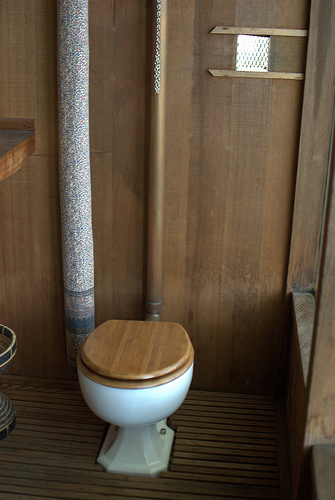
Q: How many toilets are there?
A: One.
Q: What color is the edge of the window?
A: Brown.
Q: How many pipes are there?
A: Two.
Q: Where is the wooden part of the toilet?
A: Lid.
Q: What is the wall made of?
A: Wood.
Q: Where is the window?
A: To the right.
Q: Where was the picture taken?
A: In a bathroom.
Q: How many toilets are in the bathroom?
A: 1.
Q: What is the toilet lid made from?
A: Wood.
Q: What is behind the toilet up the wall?
A: A pipe.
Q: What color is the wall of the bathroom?
A: Brown.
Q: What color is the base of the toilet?
A: White.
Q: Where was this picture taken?
A: A bathroom.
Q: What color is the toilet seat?
A: Brown.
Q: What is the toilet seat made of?
A: Wood.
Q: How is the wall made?
A: Of wood.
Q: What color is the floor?
A: Brown.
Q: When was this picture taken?
A: Daytime.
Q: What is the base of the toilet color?
A: White.